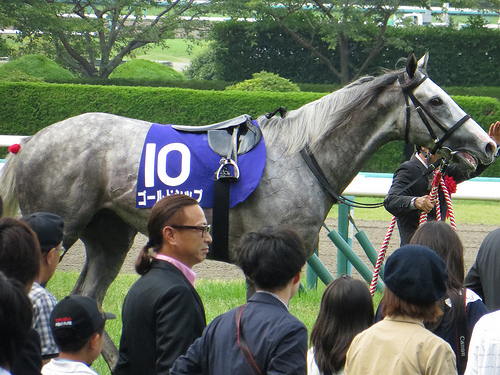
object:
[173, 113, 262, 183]
english saddle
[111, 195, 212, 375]
man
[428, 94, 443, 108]
eye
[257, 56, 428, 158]
mane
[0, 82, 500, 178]
hedge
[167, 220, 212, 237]
glasses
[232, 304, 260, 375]
strap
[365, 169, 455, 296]
rope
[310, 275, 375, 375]
hair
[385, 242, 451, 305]
beret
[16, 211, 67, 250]
beret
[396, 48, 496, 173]
head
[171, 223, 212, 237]
eye glasses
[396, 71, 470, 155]
halter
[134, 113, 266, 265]
harness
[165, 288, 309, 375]
suit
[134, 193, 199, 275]
brown hair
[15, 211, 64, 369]
person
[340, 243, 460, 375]
woman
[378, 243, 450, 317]
head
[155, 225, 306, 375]
man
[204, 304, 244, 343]
shoulder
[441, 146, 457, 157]
bit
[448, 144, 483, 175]
mouth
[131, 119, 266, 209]
pad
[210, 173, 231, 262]
strap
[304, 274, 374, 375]
woman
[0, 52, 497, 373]
horse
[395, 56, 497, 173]
face